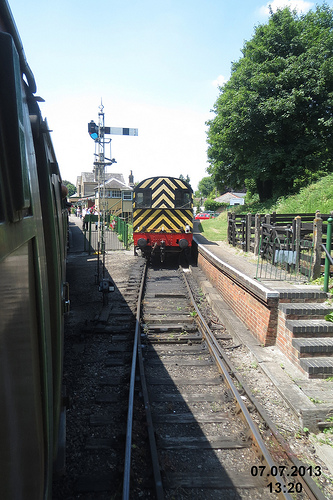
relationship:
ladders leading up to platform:
[272, 287, 332, 381] [196, 232, 318, 287]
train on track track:
[131, 175, 199, 261] [120, 257, 299, 499]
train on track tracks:
[131, 175, 195, 262] [120, 260, 325, 497]